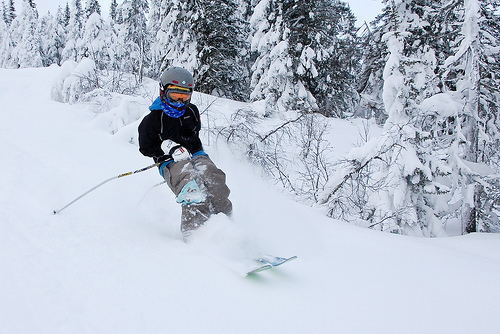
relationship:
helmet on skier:
[154, 64, 195, 107] [139, 65, 300, 281]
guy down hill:
[131, 67, 281, 268] [2, 67, 498, 327]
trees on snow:
[234, 5, 452, 235] [338, 229, 450, 280]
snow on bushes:
[41, 28, 118, 128] [234, 67, 463, 212]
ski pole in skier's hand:
[69, 170, 130, 199] [161, 140, 198, 167]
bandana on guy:
[148, 92, 185, 117] [137, 67, 232, 245]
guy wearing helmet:
[137, 67, 232, 245] [158, 65, 196, 88]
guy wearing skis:
[137, 67, 232, 245] [237, 248, 297, 282]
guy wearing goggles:
[137, 67, 232, 245] [155, 80, 194, 104]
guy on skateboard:
[137, 67, 232, 245] [190, 231, 297, 274]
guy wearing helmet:
[137, 67, 232, 245] [135, 59, 220, 128]